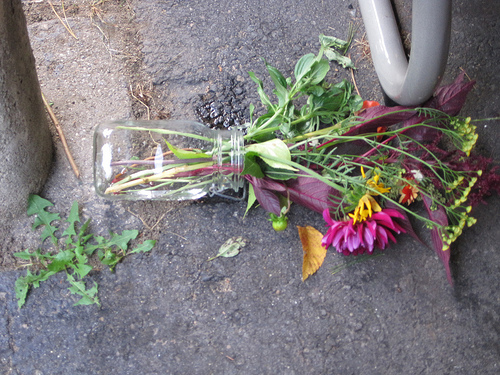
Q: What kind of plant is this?
A: Flowers.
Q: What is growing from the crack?
A: Dandelion.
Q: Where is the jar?
A: On the ground.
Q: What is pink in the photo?
A: Flowers.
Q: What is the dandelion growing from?
A: A crack.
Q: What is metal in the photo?
A: Chair leg.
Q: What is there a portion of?
A: Post.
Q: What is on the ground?
A: Jar.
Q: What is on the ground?
A: Plant.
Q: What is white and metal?
A: Bar.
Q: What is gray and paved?
A: Ground.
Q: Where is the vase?
A: On the ground.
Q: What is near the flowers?
A: Metal bar.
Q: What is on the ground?
A: Flowers.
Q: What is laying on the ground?
A: Flowers,.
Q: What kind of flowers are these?
A: Wildflowers.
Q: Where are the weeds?
A: On the left.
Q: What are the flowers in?
A: A glass jar.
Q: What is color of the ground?
A: Gray.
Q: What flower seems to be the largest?
A: The pink one.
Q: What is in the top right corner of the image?
A: A white pipe.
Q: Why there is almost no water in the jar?
A: It was spilled.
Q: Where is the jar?
A: On the ground.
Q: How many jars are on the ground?
A: One.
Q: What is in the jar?
A: Flowers.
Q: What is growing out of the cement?
A: A weed.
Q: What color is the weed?
A: Green.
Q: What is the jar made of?
A: Glass.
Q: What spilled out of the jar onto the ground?
A: Water.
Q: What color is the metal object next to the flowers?
A: Gray.